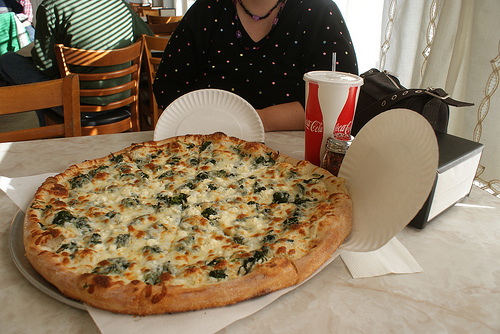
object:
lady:
[152, 2, 360, 132]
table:
[0, 130, 499, 334]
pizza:
[22, 131, 354, 317]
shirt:
[151, 0, 359, 111]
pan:
[9, 208, 88, 311]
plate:
[338, 108, 440, 253]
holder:
[406, 133, 484, 229]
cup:
[303, 71, 364, 167]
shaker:
[321, 133, 354, 177]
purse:
[350, 67, 476, 137]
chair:
[0, 74, 81, 142]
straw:
[332, 52, 336, 72]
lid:
[302, 71, 364, 88]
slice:
[138, 205, 299, 315]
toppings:
[46, 140, 325, 283]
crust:
[286, 221, 329, 255]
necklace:
[238, 0, 282, 21]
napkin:
[340, 236, 424, 278]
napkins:
[426, 152, 482, 222]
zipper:
[385, 73, 400, 89]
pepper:
[322, 138, 346, 177]